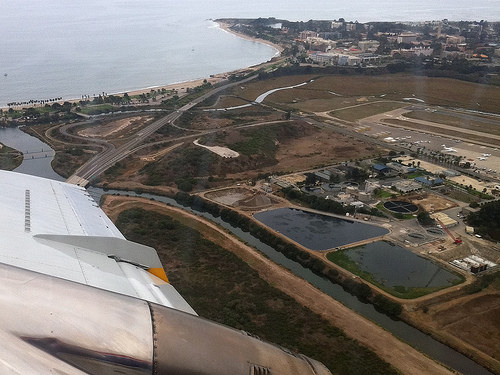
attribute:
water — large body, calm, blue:
[256, 209, 466, 304]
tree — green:
[384, 299, 406, 321]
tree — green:
[370, 288, 386, 313]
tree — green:
[352, 277, 374, 304]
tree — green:
[340, 273, 359, 295]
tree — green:
[325, 264, 342, 282]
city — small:
[244, 16, 496, 274]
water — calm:
[6, 1, 226, 63]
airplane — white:
[472, 150, 490, 166]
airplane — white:
[440, 140, 456, 155]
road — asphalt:
[73, 74, 252, 185]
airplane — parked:
[439, 140, 459, 156]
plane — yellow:
[0, 169, 335, 372]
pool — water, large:
[253, 207, 391, 254]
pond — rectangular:
[327, 239, 466, 300]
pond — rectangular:
[248, 206, 388, 251]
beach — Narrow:
[78, 69, 246, 103]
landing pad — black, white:
[380, 196, 425, 221]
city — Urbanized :
[215, 13, 497, 76]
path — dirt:
[102, 194, 449, 371]